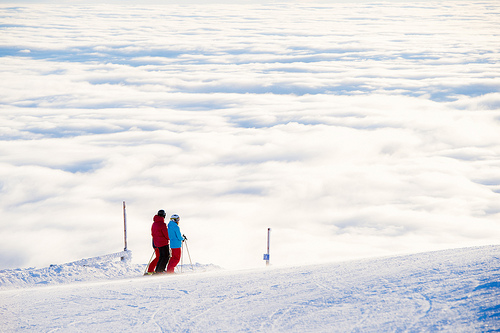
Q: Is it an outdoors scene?
A: Yes, it is outdoors.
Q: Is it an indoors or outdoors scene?
A: It is outdoors.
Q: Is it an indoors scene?
A: No, it is outdoors.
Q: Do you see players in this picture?
A: No, there are no players.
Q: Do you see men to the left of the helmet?
A: Yes, there is a man to the left of the helmet.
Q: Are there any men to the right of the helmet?
A: No, the man is to the left of the helmet.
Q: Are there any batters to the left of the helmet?
A: No, there is a man to the left of the helmet.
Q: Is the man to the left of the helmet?
A: Yes, the man is to the left of the helmet.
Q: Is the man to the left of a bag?
A: No, the man is to the left of the helmet.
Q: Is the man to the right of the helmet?
A: No, the man is to the left of the helmet.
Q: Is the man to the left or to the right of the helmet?
A: The man is to the left of the helmet.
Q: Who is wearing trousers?
A: The man is wearing trousers.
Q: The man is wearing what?
A: The man is wearing trousers.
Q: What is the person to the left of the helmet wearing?
A: The man is wearing trousers.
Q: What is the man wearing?
A: The man is wearing trousers.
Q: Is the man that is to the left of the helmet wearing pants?
A: Yes, the man is wearing pants.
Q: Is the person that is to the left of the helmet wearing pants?
A: Yes, the man is wearing pants.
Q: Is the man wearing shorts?
A: No, the man is wearing pants.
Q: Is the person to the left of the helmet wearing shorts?
A: No, the man is wearing pants.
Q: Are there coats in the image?
A: Yes, there is a coat.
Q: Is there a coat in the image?
A: Yes, there is a coat.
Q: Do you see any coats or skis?
A: Yes, there is a coat.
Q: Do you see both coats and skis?
A: Yes, there are both a coat and skis.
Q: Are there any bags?
A: No, there are no bags.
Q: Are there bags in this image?
A: No, there are no bags.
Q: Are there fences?
A: No, there are no fences.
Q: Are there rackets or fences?
A: No, there are no fences or rackets.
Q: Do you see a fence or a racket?
A: No, there are no fences or rackets.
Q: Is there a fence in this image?
A: No, there are no fences.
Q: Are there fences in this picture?
A: No, there are no fences.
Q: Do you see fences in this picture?
A: No, there are no fences.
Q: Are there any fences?
A: No, there are no fences.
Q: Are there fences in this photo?
A: No, there are no fences.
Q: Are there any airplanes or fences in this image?
A: No, there are no fences or airplanes.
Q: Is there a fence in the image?
A: No, there are no fences.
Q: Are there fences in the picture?
A: No, there are no fences.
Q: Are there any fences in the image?
A: No, there are no fences.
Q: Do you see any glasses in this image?
A: No, there are no glasses.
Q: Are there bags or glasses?
A: No, there are no glasses or bags.